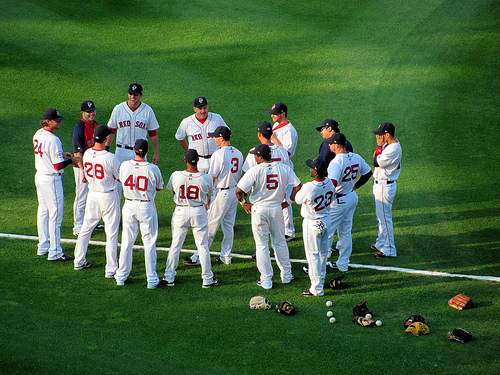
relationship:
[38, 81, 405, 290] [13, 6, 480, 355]
players gather on field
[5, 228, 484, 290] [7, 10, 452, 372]
chalk on grass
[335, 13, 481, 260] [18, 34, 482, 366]
mow lines on grass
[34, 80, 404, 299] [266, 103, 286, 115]
group wears hat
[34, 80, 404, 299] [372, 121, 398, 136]
group wears hat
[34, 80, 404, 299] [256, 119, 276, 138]
group wears hat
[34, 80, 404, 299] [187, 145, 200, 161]
group wears hat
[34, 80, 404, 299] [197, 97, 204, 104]
group wears hat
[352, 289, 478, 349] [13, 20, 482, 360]
baseball mitts on ground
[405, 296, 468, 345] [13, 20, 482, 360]
gloves on ground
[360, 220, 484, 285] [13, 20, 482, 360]
shadows on ground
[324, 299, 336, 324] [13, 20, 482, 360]
baseballs on ground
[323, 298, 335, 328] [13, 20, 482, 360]
baseballs on ground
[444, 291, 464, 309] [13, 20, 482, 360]
glove on ground